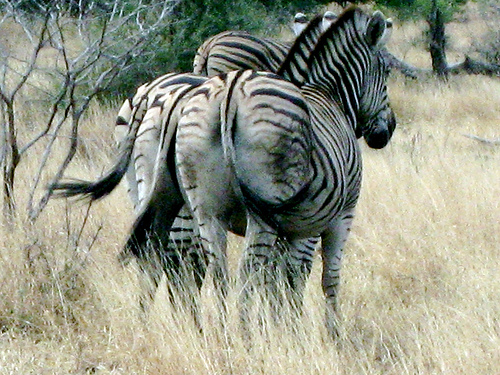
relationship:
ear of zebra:
[364, 7, 389, 47] [174, 0, 409, 344]